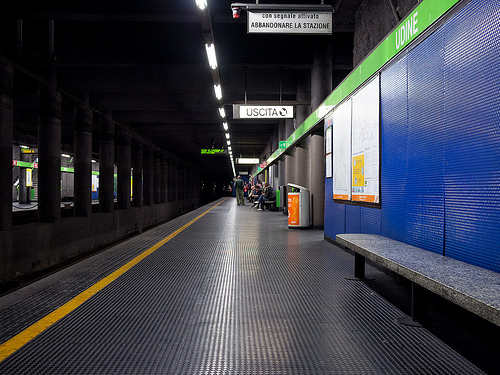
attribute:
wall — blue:
[399, 80, 459, 157]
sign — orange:
[229, 93, 296, 137]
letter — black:
[248, 22, 254, 27]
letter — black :
[260, 107, 269, 124]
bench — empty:
[334, 223, 498, 347]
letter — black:
[260, 20, 266, 28]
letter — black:
[270, 111, 274, 115]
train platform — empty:
[1, 178, 499, 368]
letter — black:
[257, 106, 267, 116]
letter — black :
[272, 22, 297, 32]